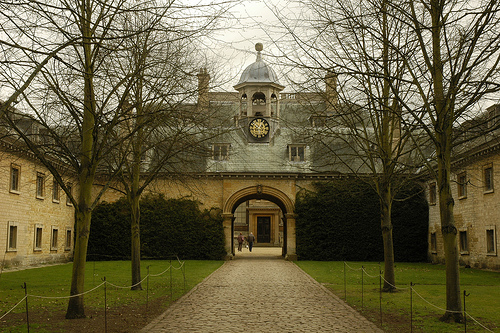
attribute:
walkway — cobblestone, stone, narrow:
[132, 248, 394, 333]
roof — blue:
[233, 42, 286, 88]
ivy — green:
[80, 190, 228, 264]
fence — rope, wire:
[0, 251, 199, 332]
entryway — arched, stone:
[222, 179, 297, 259]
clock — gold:
[246, 116, 269, 142]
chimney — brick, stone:
[196, 62, 213, 106]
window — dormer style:
[287, 142, 308, 164]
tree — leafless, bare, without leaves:
[2, 1, 260, 324]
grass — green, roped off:
[1, 260, 228, 333]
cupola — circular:
[252, 39, 268, 59]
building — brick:
[1, 97, 78, 271]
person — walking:
[244, 231, 258, 256]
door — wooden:
[255, 214, 273, 248]